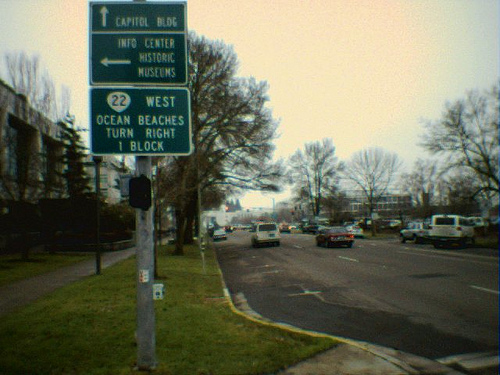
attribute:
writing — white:
[99, 15, 180, 152]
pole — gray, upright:
[125, 154, 167, 368]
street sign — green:
[83, 0, 207, 87]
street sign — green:
[84, 85, 196, 157]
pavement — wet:
[221, 239, 498, 367]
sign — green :
[89, 2, 192, 155]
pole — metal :
[133, 155, 155, 371]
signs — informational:
[48, 12, 228, 162]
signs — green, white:
[85, 0, 192, 153]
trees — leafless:
[333, 148, 403, 225]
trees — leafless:
[394, 155, 451, 226]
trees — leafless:
[413, 77, 499, 219]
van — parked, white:
[427, 213, 477, 247]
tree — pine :
[43, 113, 98, 260]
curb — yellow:
[233, 299, 297, 344]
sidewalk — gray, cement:
[2, 242, 139, 331]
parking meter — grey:
[198, 235, 210, 270]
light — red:
[220, 198, 242, 215]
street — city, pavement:
[205, 226, 497, 370]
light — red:
[347, 232, 353, 239]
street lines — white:
[327, 249, 361, 267]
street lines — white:
[461, 272, 497, 299]